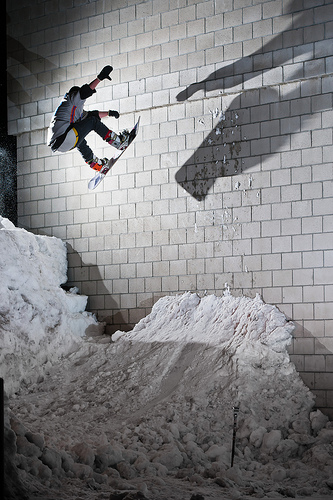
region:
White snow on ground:
[0, 216, 332, 499]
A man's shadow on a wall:
[178, 1, 332, 196]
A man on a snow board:
[47, 67, 141, 191]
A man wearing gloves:
[96, 60, 120, 118]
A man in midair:
[46, 64, 140, 191]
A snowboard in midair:
[87, 118, 144, 189]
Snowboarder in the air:
[46, 66, 141, 187]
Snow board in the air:
[87, 114, 139, 194]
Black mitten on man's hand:
[94, 68, 114, 83]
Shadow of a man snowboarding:
[178, 83, 309, 201]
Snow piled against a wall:
[113, 289, 331, 480]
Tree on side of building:
[3, 151, 20, 217]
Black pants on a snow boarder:
[75, 114, 104, 160]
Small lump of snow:
[108, 328, 125, 341]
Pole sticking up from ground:
[229, 404, 236, 469]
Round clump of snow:
[93, 440, 123, 462]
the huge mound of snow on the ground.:
[25, 289, 261, 485]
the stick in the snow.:
[223, 399, 248, 464]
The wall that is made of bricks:
[4, 119, 327, 377]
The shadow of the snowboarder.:
[161, 1, 331, 198]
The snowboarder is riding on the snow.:
[29, 57, 146, 194]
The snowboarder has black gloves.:
[95, 64, 123, 116]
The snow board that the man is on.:
[62, 114, 158, 186]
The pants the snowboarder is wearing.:
[67, 113, 109, 157]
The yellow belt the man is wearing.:
[70, 127, 80, 154]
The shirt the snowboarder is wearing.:
[38, 103, 86, 133]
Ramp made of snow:
[95, 277, 279, 441]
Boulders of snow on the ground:
[77, 429, 206, 475]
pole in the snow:
[225, 401, 241, 467]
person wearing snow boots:
[76, 125, 135, 178]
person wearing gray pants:
[73, 118, 105, 160]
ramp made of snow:
[81, 289, 294, 446]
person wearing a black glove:
[93, 65, 112, 77]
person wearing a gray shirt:
[35, 89, 84, 134]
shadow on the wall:
[148, 63, 311, 201]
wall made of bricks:
[141, 190, 319, 271]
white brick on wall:
[293, 336, 316, 358]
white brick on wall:
[312, 371, 331, 389]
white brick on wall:
[296, 370, 314, 388]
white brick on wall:
[287, 353, 304, 369]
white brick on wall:
[303, 354, 324, 370]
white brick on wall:
[314, 337, 331, 354]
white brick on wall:
[88, 264, 105, 278]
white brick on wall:
[110, 189, 129, 204]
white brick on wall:
[166, 136, 186, 150]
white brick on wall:
[101, 207, 123, 220]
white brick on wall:
[86, 232, 106, 253]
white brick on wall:
[84, 269, 108, 282]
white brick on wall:
[111, 277, 130, 296]